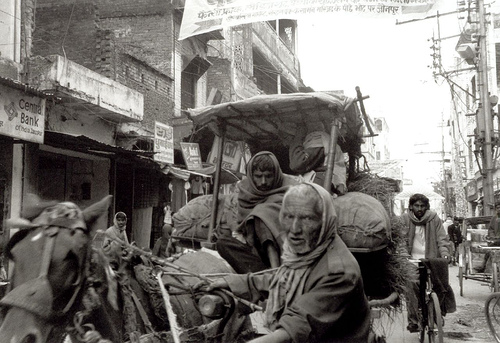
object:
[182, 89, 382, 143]
canopy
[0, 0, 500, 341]
country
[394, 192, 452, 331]
man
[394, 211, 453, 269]
coat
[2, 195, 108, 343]
gold helmet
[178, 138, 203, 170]
sign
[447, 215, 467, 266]
man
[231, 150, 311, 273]
man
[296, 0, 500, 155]
sky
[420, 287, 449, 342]
wheel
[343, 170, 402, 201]
straw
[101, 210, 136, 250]
man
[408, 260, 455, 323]
pants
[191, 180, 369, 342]
man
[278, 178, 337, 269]
robe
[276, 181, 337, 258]
head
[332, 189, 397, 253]
sacks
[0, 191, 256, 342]
horse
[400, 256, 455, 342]
bicycle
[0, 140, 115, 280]
wall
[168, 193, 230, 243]
bag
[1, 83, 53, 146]
sign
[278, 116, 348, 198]
person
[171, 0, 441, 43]
banner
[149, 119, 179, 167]
signs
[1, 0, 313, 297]
building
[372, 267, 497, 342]
street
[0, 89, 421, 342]
cart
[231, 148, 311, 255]
blanket